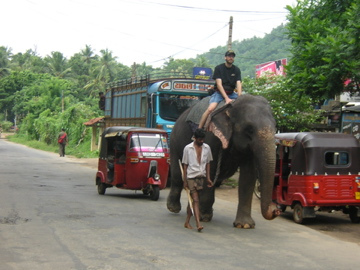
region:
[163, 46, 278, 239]
a man riding an elephant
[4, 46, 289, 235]
a man riding an elephant down the street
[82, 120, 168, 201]
a taxi in India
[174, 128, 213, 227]
a man walking with a stick in his hand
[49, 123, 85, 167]
a man walking down the street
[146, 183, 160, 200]
the front wheel of a taxi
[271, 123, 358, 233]
a black and red taxi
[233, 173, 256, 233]
the front leg of an elephant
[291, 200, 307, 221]
the rear wheel of a taxi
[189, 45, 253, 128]
a man on top of an elephant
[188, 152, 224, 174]
Man wearing a white shirt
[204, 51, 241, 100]
Man on a elephant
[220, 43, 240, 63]
Man wearing a black hat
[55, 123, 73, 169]
Man walking down the street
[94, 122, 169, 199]
Red motor cab on the street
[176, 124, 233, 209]
man holding a elephant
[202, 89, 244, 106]
Man with blue jeans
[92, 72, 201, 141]
Blue bus on the side on the road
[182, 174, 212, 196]
man wearing brown shorts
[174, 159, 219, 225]
Man holding a stick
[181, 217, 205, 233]
Man is not wearing shoes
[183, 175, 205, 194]
Man is wearing shorts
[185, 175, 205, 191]
Man is wearing brown shorts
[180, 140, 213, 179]
Man is wearing a shirt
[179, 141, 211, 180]
Man is wearing a white shirt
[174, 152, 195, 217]
Man is holding a stick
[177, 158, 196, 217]
Man is carrying a stick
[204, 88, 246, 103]
Man is wearing shorts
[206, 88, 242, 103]
Man is wearing blue shorts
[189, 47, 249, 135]
Man is riding an elephant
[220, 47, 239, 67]
the head of a man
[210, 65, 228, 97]
the arm of a man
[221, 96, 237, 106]
the hand of a man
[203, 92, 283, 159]
the head of an elephant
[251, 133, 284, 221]
the trunk of an elephant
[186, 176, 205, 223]
the leg of a man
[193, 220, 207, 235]
the foot of a man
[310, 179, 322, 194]
a red tail light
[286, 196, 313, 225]
the wheel of a car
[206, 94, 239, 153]
the ear of an elephant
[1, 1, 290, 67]
light in daytime sky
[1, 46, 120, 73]
palm leaves on tree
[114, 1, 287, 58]
black wires and pole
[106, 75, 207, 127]
front and side of truck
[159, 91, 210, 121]
window on truck windshield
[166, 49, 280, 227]
man sitting on elephant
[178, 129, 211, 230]
man walking with stick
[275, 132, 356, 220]
red vehicle with black top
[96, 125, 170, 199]
vehicle with three wheels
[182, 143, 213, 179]
open collar on shirt